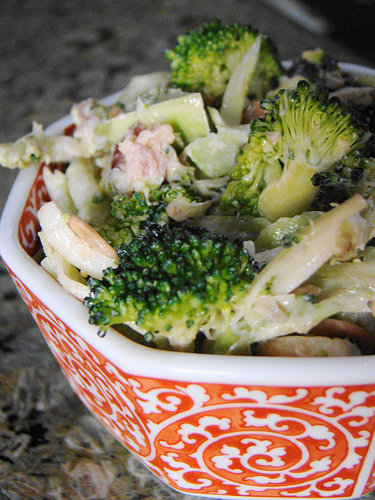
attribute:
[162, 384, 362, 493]
design — orange, white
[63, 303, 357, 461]
bowl — white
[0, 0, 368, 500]
countertop — granite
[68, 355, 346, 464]
design — orange, white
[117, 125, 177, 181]
chicken — meat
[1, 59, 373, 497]
bowl — red, white, heavy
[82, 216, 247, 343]
broccoli tops — green 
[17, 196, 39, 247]
design — orange, white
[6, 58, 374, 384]
rim — white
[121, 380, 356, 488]
design — white, orange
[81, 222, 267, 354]
piece — large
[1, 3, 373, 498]
table — brown, gray, white, black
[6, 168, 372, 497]
pattern — red and white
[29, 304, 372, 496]
design — red, orange 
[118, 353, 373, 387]
rim — white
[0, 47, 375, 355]
sauce — white